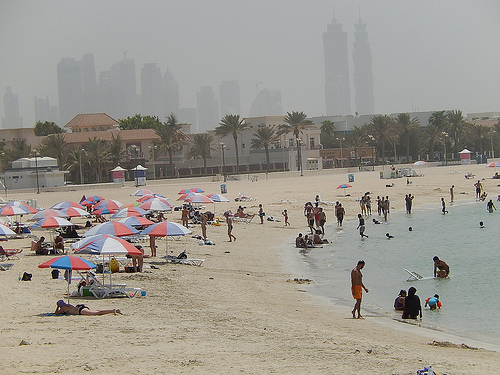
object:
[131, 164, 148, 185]
pergola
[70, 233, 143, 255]
umbrella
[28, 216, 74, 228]
umbrella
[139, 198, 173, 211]
umbrella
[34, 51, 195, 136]
buildings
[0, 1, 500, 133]
fog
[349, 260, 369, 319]
man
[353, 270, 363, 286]
trunks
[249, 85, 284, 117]
buildings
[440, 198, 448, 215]
person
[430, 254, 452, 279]
people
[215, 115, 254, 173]
palm tree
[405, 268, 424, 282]
chair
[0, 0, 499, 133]
sky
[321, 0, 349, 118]
skyscraper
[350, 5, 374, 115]
skyscraper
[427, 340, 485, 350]
sand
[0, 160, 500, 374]
beach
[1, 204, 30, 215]
umbrellas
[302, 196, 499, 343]
water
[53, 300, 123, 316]
woman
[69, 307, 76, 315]
stomach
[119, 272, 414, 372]
dirt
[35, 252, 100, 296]
umbrella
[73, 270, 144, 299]
chairs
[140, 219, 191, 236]
umbrella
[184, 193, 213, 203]
umbrella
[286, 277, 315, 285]
sand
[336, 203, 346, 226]
people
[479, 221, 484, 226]
head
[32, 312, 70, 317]
shadow